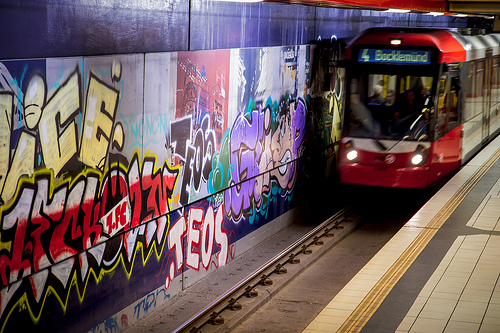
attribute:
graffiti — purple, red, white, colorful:
[1, 54, 349, 260]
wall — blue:
[5, 4, 331, 324]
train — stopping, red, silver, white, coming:
[335, 23, 500, 187]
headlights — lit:
[346, 149, 422, 169]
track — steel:
[170, 209, 386, 333]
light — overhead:
[389, 37, 408, 45]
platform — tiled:
[303, 132, 499, 332]